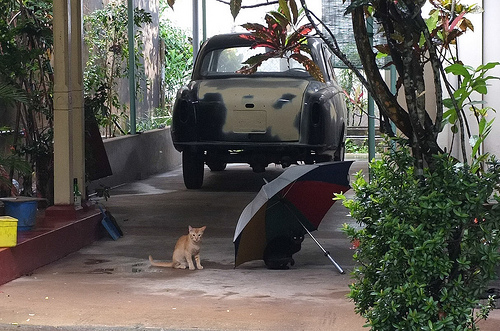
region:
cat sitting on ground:
[152, 225, 224, 281]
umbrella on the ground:
[240, 151, 355, 286]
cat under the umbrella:
[265, 227, 312, 273]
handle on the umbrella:
[310, 240, 345, 276]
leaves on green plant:
[390, 292, 415, 319]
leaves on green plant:
[426, 300, 446, 325]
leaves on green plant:
[467, 265, 492, 292]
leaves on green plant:
[395, 257, 407, 272]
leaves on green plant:
[415, 220, 430, 237]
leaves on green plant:
[444, 212, 462, 234]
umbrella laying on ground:
[230, 148, 406, 298]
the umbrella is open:
[189, 146, 394, 292]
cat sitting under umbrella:
[262, 216, 326, 288]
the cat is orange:
[158, 209, 228, 282]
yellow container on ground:
[0, 206, 32, 256]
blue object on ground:
[15, 173, 67, 244]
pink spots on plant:
[225, 6, 352, 93]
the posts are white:
[33, 0, 88, 245]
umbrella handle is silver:
[289, 210, 350, 287]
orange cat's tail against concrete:
[146, 254, 173, 266]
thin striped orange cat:
[176, 227, 203, 267]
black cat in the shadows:
[262, 228, 304, 269]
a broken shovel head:
[97, 202, 122, 238]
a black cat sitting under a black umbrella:
[245, 159, 352, 275]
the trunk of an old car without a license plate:
[198, 77, 298, 140]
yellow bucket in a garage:
[1, 218, 16, 245]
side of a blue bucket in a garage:
[14, 200, 39, 227]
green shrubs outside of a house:
[373, 218, 467, 330]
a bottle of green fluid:
[72, 176, 82, 202]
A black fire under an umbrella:
[247, 156, 355, 294]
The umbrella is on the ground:
[234, 159, 354, 275]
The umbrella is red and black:
[241, 137, 343, 283]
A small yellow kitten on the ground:
[148, 192, 226, 283]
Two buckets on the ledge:
[1, 169, 47, 252]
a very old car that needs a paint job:
[168, 22, 343, 175]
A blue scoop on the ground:
[78, 188, 135, 245]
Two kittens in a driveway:
[146, 146, 341, 297]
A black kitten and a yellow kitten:
[156, 204, 322, 304]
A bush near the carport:
[307, 140, 490, 302]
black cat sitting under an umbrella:
[227, 158, 356, 284]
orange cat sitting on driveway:
[140, 221, 215, 271]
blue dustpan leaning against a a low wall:
[95, 203, 125, 243]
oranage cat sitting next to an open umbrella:
[143, 158, 363, 290]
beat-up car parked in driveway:
[164, 22, 354, 186]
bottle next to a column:
[68, 170, 86, 214]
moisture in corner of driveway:
[90, 167, 166, 202]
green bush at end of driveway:
[337, 148, 499, 330]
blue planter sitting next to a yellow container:
[1, 186, 41, 231]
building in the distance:
[317, 1, 354, 70]